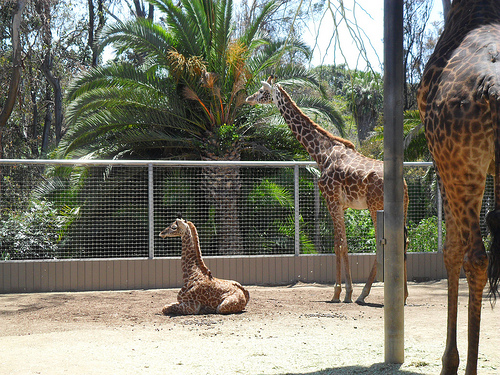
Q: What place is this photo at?
A: It is at the zoo.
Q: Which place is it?
A: It is a zoo.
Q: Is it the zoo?
A: Yes, it is the zoo.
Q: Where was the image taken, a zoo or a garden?
A: It was taken at a zoo.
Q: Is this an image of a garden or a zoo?
A: It is showing a zoo.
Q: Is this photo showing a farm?
A: No, the picture is showing a zoo.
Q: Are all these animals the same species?
A: Yes, all the animals are giraffes.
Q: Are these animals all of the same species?
A: Yes, all the animals are giraffes.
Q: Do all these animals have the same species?
A: Yes, all the animals are giraffes.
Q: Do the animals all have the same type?
A: Yes, all the animals are giraffes.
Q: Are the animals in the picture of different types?
A: No, all the animals are giraffes.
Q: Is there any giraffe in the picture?
A: Yes, there is a giraffe.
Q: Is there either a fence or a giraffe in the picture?
A: Yes, there is a giraffe.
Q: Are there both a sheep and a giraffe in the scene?
A: No, there is a giraffe but no sheep.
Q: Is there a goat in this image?
A: No, there are no goats.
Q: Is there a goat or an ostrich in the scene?
A: No, there are no goats or ostriches.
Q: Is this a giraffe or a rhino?
A: This is a giraffe.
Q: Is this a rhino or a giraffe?
A: This is a giraffe.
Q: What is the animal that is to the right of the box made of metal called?
A: The animal is a giraffe.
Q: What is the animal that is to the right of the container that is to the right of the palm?
A: The animal is a giraffe.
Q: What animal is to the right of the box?
A: The animal is a giraffe.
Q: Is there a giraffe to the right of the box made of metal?
A: Yes, there is a giraffe to the right of the box.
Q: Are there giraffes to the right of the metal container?
A: Yes, there is a giraffe to the right of the box.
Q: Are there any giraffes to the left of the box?
A: No, the giraffe is to the right of the box.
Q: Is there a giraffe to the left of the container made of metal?
A: No, the giraffe is to the right of the box.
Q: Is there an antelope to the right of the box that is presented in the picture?
A: No, there is a giraffe to the right of the box.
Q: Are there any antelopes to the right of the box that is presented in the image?
A: No, there is a giraffe to the right of the box.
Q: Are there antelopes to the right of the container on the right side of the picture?
A: No, there is a giraffe to the right of the box.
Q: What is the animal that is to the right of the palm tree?
A: The animal is a giraffe.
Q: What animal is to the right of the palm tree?
A: The animal is a giraffe.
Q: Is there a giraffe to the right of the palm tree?
A: Yes, there is a giraffe to the right of the palm tree.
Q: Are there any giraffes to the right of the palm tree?
A: Yes, there is a giraffe to the right of the palm tree.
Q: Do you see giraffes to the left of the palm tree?
A: No, the giraffe is to the right of the palm tree.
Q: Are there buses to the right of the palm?
A: No, there is a giraffe to the right of the palm.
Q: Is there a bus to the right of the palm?
A: No, there is a giraffe to the right of the palm.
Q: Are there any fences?
A: Yes, there is a fence.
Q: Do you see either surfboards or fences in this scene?
A: Yes, there is a fence.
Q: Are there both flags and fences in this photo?
A: No, there is a fence but no flags.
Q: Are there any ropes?
A: No, there are no ropes.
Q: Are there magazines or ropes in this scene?
A: No, there are no ropes or magazines.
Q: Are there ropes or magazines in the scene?
A: No, there are no ropes or magazines.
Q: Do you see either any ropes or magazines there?
A: No, there are no ropes or magazines.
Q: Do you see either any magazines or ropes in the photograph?
A: No, there are no ropes or magazines.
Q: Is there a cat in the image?
A: No, there are no cats.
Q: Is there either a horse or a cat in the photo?
A: No, there are no cats or horses.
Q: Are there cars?
A: No, there are no cars.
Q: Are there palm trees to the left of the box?
A: Yes, there is a palm tree to the left of the box.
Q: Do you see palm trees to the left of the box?
A: Yes, there is a palm tree to the left of the box.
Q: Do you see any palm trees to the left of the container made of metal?
A: Yes, there is a palm tree to the left of the box.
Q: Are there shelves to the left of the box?
A: No, there is a palm tree to the left of the box.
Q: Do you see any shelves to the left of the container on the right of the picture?
A: No, there is a palm tree to the left of the box.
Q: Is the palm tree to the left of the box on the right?
A: Yes, the palm tree is to the left of the box.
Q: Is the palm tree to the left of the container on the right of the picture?
A: Yes, the palm tree is to the left of the box.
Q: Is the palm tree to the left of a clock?
A: No, the palm tree is to the left of the box.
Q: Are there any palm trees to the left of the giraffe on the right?
A: Yes, there is a palm tree to the left of the giraffe.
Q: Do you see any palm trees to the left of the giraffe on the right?
A: Yes, there is a palm tree to the left of the giraffe.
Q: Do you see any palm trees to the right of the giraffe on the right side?
A: No, the palm tree is to the left of the giraffe.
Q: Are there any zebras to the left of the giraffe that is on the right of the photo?
A: No, there is a palm tree to the left of the giraffe.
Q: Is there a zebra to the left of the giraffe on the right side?
A: No, there is a palm tree to the left of the giraffe.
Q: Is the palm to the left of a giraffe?
A: Yes, the palm is to the left of a giraffe.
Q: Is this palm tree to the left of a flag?
A: No, the palm tree is to the left of a giraffe.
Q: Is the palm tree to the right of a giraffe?
A: No, the palm tree is to the left of a giraffe.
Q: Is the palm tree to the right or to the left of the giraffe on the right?
A: The palm tree is to the left of the giraffe.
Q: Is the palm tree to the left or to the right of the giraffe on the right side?
A: The palm tree is to the left of the giraffe.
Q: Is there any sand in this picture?
A: Yes, there is sand.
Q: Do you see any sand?
A: Yes, there is sand.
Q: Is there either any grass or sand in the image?
A: Yes, there is sand.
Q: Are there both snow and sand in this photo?
A: No, there is sand but no snow.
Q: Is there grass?
A: No, there is no grass.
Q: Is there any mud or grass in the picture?
A: No, there are no grass or mud.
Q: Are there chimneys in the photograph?
A: No, there are no chimneys.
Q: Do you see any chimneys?
A: No, there are no chimneys.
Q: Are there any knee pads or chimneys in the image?
A: No, there are no chimneys or knee pads.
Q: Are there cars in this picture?
A: No, there are no cars.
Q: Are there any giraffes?
A: Yes, there is a giraffe.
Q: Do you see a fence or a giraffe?
A: Yes, there is a giraffe.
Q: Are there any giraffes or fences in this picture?
A: Yes, there is a giraffe.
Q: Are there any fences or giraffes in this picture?
A: Yes, there is a giraffe.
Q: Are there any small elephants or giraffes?
A: Yes, there is a small giraffe.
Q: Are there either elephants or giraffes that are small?
A: Yes, the giraffe is small.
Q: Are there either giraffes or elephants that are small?
A: Yes, the giraffe is small.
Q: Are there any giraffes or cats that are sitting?
A: Yes, the giraffe is sitting.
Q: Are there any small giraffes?
A: Yes, there is a small giraffe.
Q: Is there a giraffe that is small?
A: Yes, there is a giraffe that is small.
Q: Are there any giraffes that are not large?
A: Yes, there is a small giraffe.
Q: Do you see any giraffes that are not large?
A: Yes, there is a small giraffe.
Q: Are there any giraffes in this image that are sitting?
A: Yes, there is a giraffe that is sitting.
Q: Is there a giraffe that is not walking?
A: Yes, there is a giraffe that is sitting.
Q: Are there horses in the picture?
A: No, there are no horses.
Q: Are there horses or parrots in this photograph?
A: No, there are no horses or parrots.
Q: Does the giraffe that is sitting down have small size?
A: Yes, the giraffe is small.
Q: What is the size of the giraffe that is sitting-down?
A: The giraffe is small.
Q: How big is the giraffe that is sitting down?
A: The giraffe is small.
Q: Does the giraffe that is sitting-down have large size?
A: No, the giraffe is small.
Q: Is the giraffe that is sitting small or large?
A: The giraffe is small.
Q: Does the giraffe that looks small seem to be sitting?
A: Yes, the giraffe is sitting.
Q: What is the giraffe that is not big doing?
A: The giraffe is sitting.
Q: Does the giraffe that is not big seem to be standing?
A: No, the giraffe is sitting.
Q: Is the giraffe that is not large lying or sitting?
A: The giraffe is sitting.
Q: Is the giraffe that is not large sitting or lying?
A: The giraffe is sitting.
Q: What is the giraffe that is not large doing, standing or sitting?
A: The giraffe is sitting.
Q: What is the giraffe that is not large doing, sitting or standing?
A: The giraffe is sitting.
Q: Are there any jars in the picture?
A: No, there are no jars.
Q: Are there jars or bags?
A: No, there are no jars or bags.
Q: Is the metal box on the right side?
A: Yes, the box is on the right of the image.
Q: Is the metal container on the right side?
A: Yes, the box is on the right of the image.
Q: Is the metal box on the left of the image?
A: No, the box is on the right of the image.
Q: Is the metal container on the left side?
A: No, the box is on the right of the image.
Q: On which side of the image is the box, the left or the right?
A: The box is on the right of the image.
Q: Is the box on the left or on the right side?
A: The box is on the right of the image.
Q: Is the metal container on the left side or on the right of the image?
A: The box is on the right of the image.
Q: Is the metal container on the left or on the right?
A: The box is on the right of the image.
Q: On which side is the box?
A: The box is on the right of the image.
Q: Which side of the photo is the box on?
A: The box is on the right of the image.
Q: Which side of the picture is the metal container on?
A: The box is on the right of the image.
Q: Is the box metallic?
A: Yes, the box is metallic.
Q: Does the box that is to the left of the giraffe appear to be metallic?
A: Yes, the box is metallic.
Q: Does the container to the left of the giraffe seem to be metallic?
A: Yes, the box is metallic.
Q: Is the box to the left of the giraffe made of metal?
A: Yes, the box is made of metal.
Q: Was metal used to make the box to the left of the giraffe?
A: Yes, the box is made of metal.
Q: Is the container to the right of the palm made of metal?
A: Yes, the box is made of metal.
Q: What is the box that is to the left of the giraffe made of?
A: The box is made of metal.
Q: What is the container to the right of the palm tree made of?
A: The box is made of metal.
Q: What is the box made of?
A: The box is made of metal.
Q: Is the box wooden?
A: No, the box is metallic.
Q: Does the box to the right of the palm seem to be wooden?
A: No, the box is metallic.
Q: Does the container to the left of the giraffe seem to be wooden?
A: No, the box is metallic.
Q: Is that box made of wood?
A: No, the box is made of metal.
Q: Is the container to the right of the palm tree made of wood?
A: No, the box is made of metal.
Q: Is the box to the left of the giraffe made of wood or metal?
A: The box is made of metal.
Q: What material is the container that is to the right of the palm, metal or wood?
A: The box is made of metal.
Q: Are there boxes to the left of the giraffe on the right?
A: Yes, there is a box to the left of the giraffe.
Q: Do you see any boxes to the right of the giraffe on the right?
A: No, the box is to the left of the giraffe.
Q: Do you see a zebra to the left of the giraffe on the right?
A: No, there is a box to the left of the giraffe.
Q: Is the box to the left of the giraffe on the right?
A: Yes, the box is to the left of the giraffe.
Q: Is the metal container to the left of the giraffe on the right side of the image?
A: Yes, the box is to the left of the giraffe.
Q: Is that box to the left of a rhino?
A: No, the box is to the left of the giraffe.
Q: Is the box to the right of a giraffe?
A: No, the box is to the left of a giraffe.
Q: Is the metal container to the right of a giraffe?
A: No, the box is to the left of a giraffe.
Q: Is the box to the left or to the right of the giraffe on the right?
A: The box is to the left of the giraffe.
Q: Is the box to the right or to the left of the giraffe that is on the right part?
A: The box is to the left of the giraffe.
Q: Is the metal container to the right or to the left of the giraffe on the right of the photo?
A: The box is to the left of the giraffe.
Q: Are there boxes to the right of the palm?
A: Yes, there is a box to the right of the palm.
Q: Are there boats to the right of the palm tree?
A: No, there is a box to the right of the palm tree.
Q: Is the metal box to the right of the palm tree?
A: Yes, the box is to the right of the palm tree.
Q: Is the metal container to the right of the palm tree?
A: Yes, the box is to the right of the palm tree.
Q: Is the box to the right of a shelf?
A: No, the box is to the right of the palm tree.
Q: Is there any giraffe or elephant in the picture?
A: Yes, there is a giraffe.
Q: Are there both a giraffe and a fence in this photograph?
A: Yes, there are both a giraffe and a fence.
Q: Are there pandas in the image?
A: No, there are no pandas.